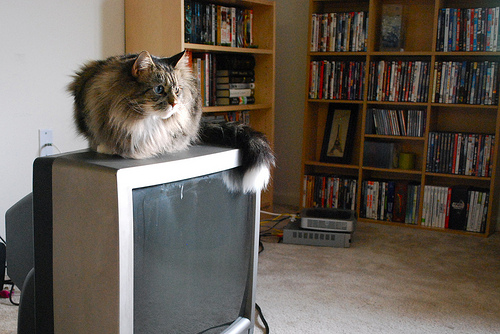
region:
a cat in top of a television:
[17, 46, 279, 332]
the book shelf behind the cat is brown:
[121, 0, 278, 221]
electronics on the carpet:
[272, 204, 367, 253]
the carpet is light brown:
[263, 206, 498, 332]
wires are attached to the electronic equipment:
[260, 205, 307, 247]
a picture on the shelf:
[307, 96, 362, 166]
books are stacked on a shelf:
[211, 52, 266, 109]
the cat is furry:
[63, 38, 280, 198]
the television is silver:
[5, 132, 265, 332]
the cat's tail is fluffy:
[196, 117, 278, 194]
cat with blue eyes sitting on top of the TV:
[65, 43, 248, 157]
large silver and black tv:
[6, 150, 264, 327]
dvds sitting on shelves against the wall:
[311, 8, 377, 105]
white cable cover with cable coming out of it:
[31, 120, 57, 157]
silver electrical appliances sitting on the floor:
[271, 200, 355, 247]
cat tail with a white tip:
[200, 119, 277, 191]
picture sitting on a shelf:
[304, 96, 364, 167]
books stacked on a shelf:
[211, 52, 265, 109]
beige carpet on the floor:
[291, 243, 427, 306]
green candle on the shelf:
[393, 146, 419, 168]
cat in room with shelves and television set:
[23, 10, 483, 316]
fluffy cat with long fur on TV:
[60, 45, 275, 190]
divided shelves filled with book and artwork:
[305, 5, 495, 226]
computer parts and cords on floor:
[262, 205, 353, 250]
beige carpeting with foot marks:
[272, 240, 487, 322]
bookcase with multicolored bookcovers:
[185, 2, 275, 197]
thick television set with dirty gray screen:
[10, 155, 260, 330]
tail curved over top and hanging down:
[190, 101, 271, 191]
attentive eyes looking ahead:
[150, 75, 180, 117]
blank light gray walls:
[7, 5, 69, 125]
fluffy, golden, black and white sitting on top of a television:
[63, 48, 280, 196]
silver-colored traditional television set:
[4, 139, 265, 332]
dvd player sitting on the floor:
[281, 226, 353, 248]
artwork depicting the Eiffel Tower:
[318, 103, 356, 164]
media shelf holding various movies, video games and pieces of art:
[298, 2, 499, 235]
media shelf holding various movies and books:
[123, 0, 275, 220]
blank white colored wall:
[1, 0, 123, 241]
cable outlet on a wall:
[38, 129, 55, 155]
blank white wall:
[276, 0, 306, 205]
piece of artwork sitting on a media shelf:
[378, 0, 405, 55]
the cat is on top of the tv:
[106, 57, 201, 217]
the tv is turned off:
[68, 188, 240, 275]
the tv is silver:
[76, 224, 112, 284]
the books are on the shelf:
[213, 65, 265, 110]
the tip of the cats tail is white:
[239, 156, 287, 206]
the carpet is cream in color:
[338, 268, 428, 331]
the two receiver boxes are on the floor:
[305, 211, 362, 255]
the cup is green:
[393, 145, 416, 179]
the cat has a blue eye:
[149, 77, 169, 101]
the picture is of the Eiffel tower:
[323, 113, 348, 172]